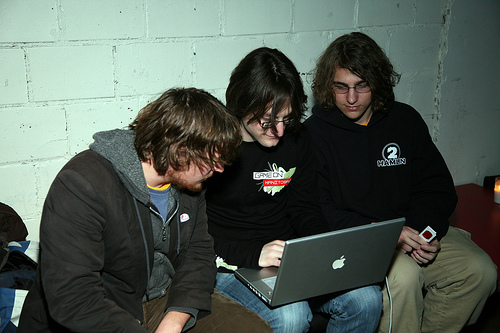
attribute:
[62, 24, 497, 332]
men — young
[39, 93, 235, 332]
man — young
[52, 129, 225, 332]
hoody — grey, brown, gray, dark gray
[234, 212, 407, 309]
computer — grey, a laptop, silver, apple, gray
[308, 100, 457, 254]
hoody — black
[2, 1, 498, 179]
cinder blocks — white, cinder block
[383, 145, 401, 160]
number — 2, white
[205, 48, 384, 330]
man — young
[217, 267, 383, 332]
jeans — blue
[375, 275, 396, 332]
power cord — white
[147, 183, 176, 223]
tee shirt — blue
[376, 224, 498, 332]
pants — tan, khaki, beige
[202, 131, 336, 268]
sweat shirt — black